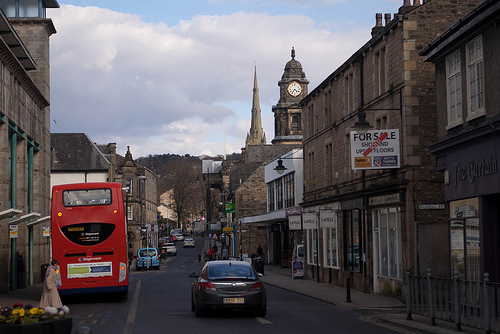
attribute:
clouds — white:
[55, 4, 328, 123]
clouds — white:
[32, 57, 162, 121]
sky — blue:
[69, 19, 290, 174]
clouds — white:
[168, 93, 227, 146]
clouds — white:
[193, 15, 251, 62]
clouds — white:
[113, 10, 174, 49]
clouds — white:
[56, 26, 114, 66]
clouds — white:
[301, 27, 337, 54]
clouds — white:
[176, 16, 282, 81]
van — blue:
[138, 228, 171, 280]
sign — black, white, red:
[342, 129, 407, 174]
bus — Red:
[49, 180, 131, 295]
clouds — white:
[73, 25, 242, 140]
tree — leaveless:
[160, 153, 208, 230]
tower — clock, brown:
[279, 45, 314, 117]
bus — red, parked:
[28, 144, 139, 314]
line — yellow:
[128, 273, 147, 327]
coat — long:
[44, 266, 64, 304]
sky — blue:
[48, 0, 381, 157]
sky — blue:
[38, 6, 385, 164]